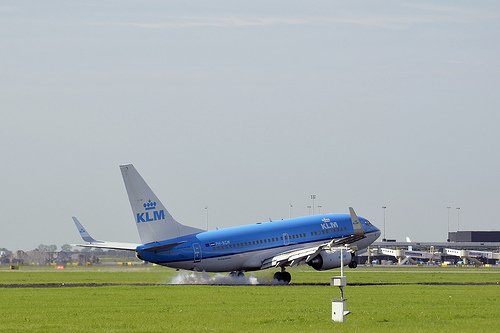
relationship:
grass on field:
[0, 265, 500, 330] [1, 267, 496, 331]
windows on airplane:
[204, 231, 312, 248] [54, 151, 394, 312]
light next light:
[451, 205, 461, 210] [445, 204, 450, 211]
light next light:
[379, 204, 387, 211] [309, 193, 316, 200]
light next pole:
[315, 204, 322, 209] [457, 211, 461, 231]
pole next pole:
[382, 208, 385, 240] [310, 196, 315, 217]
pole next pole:
[310, 196, 315, 217] [315, 207, 320, 215]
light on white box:
[331, 247, 348, 324] [332, 247, 349, 322]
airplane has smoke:
[54, 151, 394, 312] [159, 265, 291, 292]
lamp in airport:
[399, 232, 413, 258] [5, 228, 498, 326]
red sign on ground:
[52, 260, 69, 275] [12, 267, 492, 331]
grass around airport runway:
[0, 265, 500, 330] [0, 250, 498, 325]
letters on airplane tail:
[133, 206, 167, 225] [114, 152, 204, 242]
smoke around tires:
[168, 267, 271, 286] [274, 270, 288, 286]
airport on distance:
[0, 222, 498, 331] [10, 234, 498, 272]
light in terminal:
[379, 204, 389, 211] [340, 220, 498, 275]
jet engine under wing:
[297, 239, 371, 277] [239, 203, 376, 273]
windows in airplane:
[206, 221, 350, 252] [86, 164, 406, 304]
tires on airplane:
[266, 269, 297, 288] [64, 157, 385, 291]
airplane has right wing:
[54, 151, 394, 312] [263, 207, 358, 267]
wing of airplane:
[56, 213, 148, 259] [54, 151, 394, 312]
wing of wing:
[239, 203, 376, 273] [56, 213, 148, 259]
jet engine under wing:
[308, 244, 355, 269] [331, 207, 366, 242]